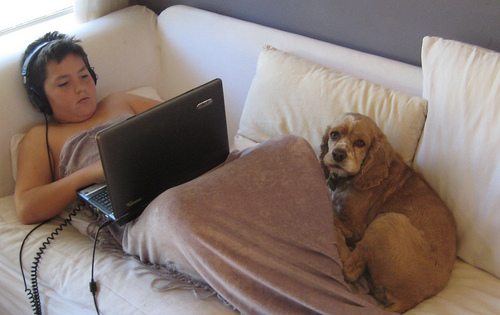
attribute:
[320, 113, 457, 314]
dog — laying, brown, looking, staring, mix, cocker spaniel, white, blond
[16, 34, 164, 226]
boy — shirtless, adolescent, resting, writing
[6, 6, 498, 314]
couch — white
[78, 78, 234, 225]
laptop — black, open, grey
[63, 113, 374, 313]
blanket — wrapped, pink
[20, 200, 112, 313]
cords — hanging, black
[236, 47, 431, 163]
pillow — white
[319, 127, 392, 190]
dogs ears — floppy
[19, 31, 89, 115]
hair — messy, brown, shaggy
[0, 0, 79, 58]
window — behind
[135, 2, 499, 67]
wall — blue